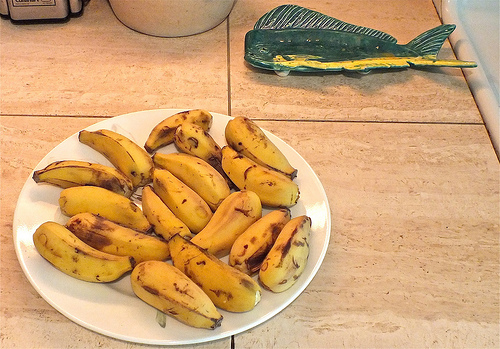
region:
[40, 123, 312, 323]
Cut bananas on the plate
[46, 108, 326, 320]
A plate below the banans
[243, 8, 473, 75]
A piece of a fish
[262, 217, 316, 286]
The banans have black marks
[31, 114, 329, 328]
The plate is circular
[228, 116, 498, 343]
A square tile on the counter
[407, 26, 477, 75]
The tail of the fish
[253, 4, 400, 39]
The fish had a green fin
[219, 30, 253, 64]
The head of the fish is cut off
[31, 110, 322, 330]
The bananas are yellow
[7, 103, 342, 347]
bananas on a plate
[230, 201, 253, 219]
brown spot on the banana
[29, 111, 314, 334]
a bunch of yellow bananas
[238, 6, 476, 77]
a figurine of a fish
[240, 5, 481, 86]
green and yellow fish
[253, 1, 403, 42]
fins on the top of the fish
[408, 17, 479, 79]
fins of the tail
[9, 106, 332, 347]
round white plate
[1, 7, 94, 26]
black line on the bottom of the silver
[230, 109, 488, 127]
thin line separaing the tiles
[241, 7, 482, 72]
A fish on the floor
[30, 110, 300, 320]
Bananas in the photo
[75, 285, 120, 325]
A plate on the floor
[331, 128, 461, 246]
Tiles on the floor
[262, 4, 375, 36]
Gills on the fish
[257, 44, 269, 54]
Fish eye in the photo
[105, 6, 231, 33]
A pan in the background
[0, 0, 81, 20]
Blender in the photo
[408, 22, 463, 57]
A fish tail in the photo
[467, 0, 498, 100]
A wall in the photo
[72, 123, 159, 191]
small banana on a plate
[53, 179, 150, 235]
small banana on a plate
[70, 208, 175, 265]
small banana on a plate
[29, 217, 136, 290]
small banana on a plate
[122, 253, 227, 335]
small banana on a plate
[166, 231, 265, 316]
small banana on a plate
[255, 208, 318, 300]
small banana on a plate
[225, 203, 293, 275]
small banana on a plate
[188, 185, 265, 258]
small banana on a plate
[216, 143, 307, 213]
small banana on a plate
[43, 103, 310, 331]
yellow food product on white plate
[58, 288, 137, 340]
white plate bottom of yellow food product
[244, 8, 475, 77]
a green fish decoration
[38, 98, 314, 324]
yellow food product with brown bruising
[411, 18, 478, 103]
tail of the fish decoration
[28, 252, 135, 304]
shadow from the yellow food product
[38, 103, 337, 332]
banana-like food product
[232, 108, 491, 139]
line separating the tiles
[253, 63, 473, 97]
shadow from the fish decoration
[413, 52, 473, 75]
yellow part of the fish tail decoration